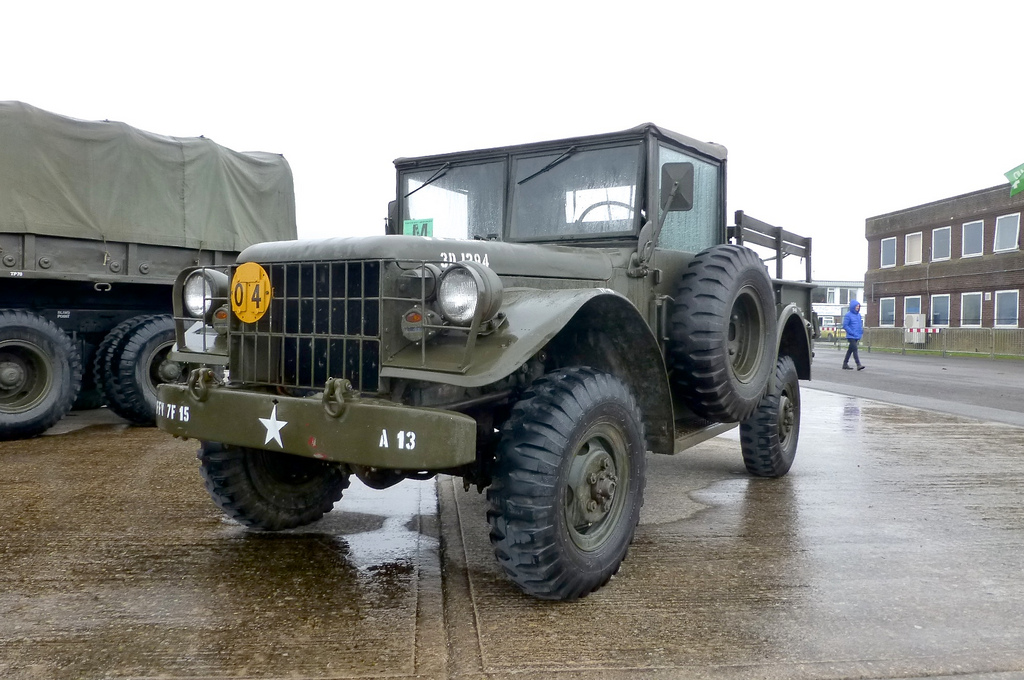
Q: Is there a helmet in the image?
A: No, there are no helmets.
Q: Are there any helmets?
A: No, there are no helmets.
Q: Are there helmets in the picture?
A: No, there are no helmets.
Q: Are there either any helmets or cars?
A: No, there are no helmets or cars.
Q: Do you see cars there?
A: No, there are no cars.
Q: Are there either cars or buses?
A: No, there are no cars or buses.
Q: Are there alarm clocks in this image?
A: No, there are no alarm clocks.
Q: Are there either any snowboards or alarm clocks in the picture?
A: No, there are no alarm clocks or snowboards.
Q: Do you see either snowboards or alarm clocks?
A: No, there are no alarm clocks or snowboards.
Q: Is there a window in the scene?
A: Yes, there are windows.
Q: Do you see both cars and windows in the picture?
A: No, there are windows but no cars.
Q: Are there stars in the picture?
A: Yes, there is a star.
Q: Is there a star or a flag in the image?
A: Yes, there is a star.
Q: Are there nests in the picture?
A: No, there are no nests.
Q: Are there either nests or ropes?
A: No, there are no nests or ropes.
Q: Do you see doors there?
A: Yes, there is a door.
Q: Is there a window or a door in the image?
A: Yes, there is a door.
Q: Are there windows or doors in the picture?
A: Yes, there is a door.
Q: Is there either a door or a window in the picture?
A: Yes, there is a door.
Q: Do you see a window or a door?
A: Yes, there is a door.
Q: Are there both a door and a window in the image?
A: Yes, there are both a door and a window.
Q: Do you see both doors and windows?
A: Yes, there are both a door and a window.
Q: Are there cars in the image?
A: No, there are no cars.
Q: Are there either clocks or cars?
A: No, there are no cars or clocks.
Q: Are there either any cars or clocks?
A: No, there are no cars or clocks.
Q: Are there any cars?
A: No, there are no cars.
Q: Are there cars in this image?
A: No, there are no cars.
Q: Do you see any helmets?
A: No, there are no helmets.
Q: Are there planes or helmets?
A: No, there are no helmets or planes.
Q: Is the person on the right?
A: Yes, the person is on the right of the image.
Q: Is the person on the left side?
A: No, the person is on the right of the image.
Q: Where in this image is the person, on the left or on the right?
A: The person is on the right of the image.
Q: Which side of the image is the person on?
A: The person is on the right of the image.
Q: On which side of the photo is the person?
A: The person is on the right of the image.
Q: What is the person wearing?
A: The person is wearing a jacket.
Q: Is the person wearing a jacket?
A: Yes, the person is wearing a jacket.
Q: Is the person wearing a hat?
A: No, the person is wearing a jacket.